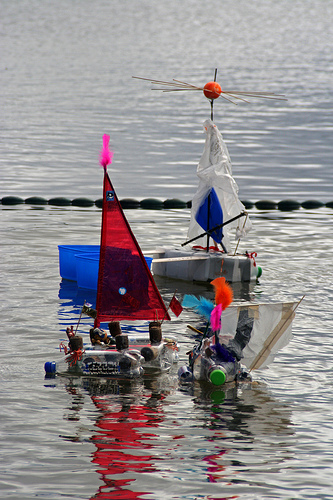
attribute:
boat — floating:
[53, 140, 171, 380]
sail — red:
[91, 169, 172, 325]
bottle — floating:
[40, 348, 144, 379]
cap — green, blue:
[44, 363, 54, 379]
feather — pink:
[104, 136, 110, 169]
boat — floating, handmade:
[153, 65, 260, 286]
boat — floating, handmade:
[190, 280, 303, 389]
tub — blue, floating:
[57, 245, 130, 283]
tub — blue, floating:
[75, 255, 152, 291]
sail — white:
[181, 123, 245, 254]